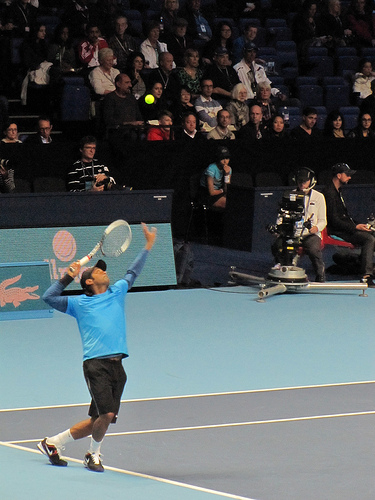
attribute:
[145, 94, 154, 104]
tennis ball — in air, yellow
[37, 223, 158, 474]
tennis player — in position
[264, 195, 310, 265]
camera — professional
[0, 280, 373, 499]
tennis court — grey, blue, gray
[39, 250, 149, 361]
shirt — blue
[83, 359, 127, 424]
shorts — black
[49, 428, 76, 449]
sock — white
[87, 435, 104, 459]
sock — white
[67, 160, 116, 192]
sweater — white, black, white striped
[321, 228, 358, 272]
chair — red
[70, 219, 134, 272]
racket — white, tan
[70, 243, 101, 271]
handle — white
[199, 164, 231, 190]
shirt — blue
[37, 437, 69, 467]
shoe — black, nike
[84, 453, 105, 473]
shoe — black, nike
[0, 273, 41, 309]
logo — alligator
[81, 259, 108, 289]
cap — dark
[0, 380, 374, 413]
line — white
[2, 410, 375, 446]
line — white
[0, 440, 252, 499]
line — white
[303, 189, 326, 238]
shirt — white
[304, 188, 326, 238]
jacket — white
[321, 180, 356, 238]
jacket — black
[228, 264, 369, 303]
support — mobile